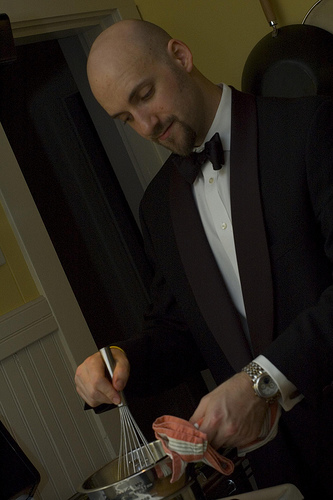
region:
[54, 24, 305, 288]
bald man in tux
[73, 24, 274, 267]
man wearing tuxedo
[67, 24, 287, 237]
man wearing bowtie in photo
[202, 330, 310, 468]
man wearing silver wrist watch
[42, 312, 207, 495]
man using a whisk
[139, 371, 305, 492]
man using orange and white towel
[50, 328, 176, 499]
whisk in a silver bowl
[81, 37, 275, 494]
man using a whisk in a silver bowl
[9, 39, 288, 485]
doorway in a background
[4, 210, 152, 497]
white and yellow wall in background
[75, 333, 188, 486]
a silver wire whisk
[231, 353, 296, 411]
a fancy metal watch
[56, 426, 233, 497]
a silver metal mixing bowl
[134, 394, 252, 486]
a colorful kitchen towel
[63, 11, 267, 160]
a young bald man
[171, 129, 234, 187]
a formal black bowtie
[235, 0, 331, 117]
a metal kitchen skillet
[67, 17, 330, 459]
man in a black tuxedo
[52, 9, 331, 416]
bald man in a tuxedo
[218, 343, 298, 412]
an expensive silver watch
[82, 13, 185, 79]
Man has a bald head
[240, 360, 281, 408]
Man is wearing a silver wrist watch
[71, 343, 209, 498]
Man is mixing something in a silver pot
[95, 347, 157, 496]
Man is holding a silver whisk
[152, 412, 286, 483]
Man is holding the pot with an orange dish rag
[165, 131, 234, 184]
Man is wearing a black bow tie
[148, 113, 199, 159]
Man has a goatee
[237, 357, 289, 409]
Man is wearing a wristwatch with dials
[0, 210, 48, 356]
The wall is painted yellow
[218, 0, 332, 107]
A pan is hanging on the wall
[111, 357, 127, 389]
a thumb of a hand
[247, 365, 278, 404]
a watch o a wrist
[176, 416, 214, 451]
a hand holding a towel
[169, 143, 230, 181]
a black bow tie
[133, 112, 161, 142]
a nose on a face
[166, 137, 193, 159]
a beard on a man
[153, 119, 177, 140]
a mustache of a man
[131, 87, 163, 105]
an eye of a man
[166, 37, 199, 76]
an ear of a man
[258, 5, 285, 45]
a wooden handle of a pan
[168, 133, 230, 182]
black bow tie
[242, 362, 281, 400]
silver watch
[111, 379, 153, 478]
mixing utensil in a silver bowl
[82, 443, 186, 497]
silver bowl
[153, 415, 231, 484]
orange and white cloth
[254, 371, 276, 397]
white and silver watch face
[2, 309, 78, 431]
white wall with lines on it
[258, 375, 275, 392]
circles on the clocks face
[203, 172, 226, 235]
two small white buttons on the shirt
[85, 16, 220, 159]
bald headed man